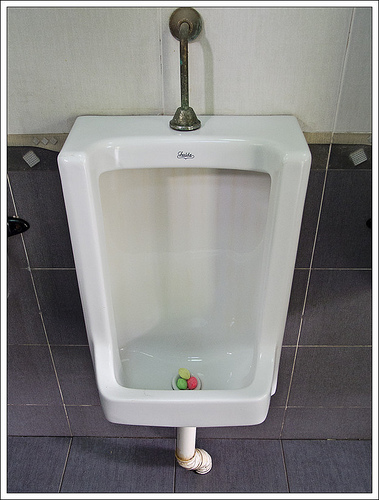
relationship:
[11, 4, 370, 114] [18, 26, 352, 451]
off-white tiles in bathroom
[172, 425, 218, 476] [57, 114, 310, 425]
pipe behind toilet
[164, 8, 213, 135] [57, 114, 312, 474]
flush pipe on top of toilet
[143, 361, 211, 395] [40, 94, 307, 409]
balls on toilet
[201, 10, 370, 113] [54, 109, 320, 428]
wall above urinal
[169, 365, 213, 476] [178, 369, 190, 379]
drain under urinal cakes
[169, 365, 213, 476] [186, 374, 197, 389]
drain under urinal cakes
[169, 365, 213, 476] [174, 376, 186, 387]
drain under cake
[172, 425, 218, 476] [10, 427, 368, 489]
pipe in floor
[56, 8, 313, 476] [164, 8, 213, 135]
bathroom has flush pipe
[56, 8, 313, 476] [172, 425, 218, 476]
bathroom has pipe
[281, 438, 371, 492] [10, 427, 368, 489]
tile on floor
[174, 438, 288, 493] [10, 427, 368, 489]
tile on floor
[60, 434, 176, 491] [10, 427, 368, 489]
tile on floor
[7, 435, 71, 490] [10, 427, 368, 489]
tile on floor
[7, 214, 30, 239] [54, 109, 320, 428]
object near urinal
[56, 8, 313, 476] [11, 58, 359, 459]
bathroom mounted on wall